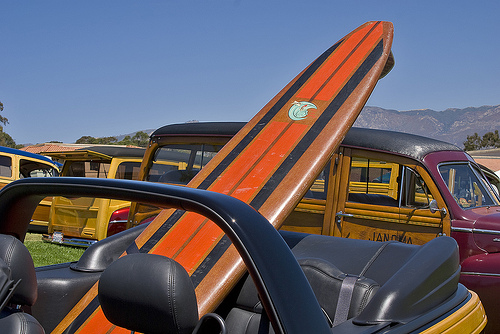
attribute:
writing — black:
[366, 229, 413, 248]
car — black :
[27, 178, 454, 332]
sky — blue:
[76, 20, 226, 89]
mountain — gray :
[114, 106, 498, 149]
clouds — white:
[187, 60, 273, 82]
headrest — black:
[84, 256, 226, 326]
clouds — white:
[11, 28, 61, 78]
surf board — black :
[51, 20, 408, 329]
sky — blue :
[100, 88, 130, 110]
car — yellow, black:
[128, 229, 477, 331]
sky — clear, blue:
[69, 20, 301, 91]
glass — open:
[38, 150, 113, 162]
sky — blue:
[1, 8, 490, 106]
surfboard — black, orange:
[40, 16, 395, 332]